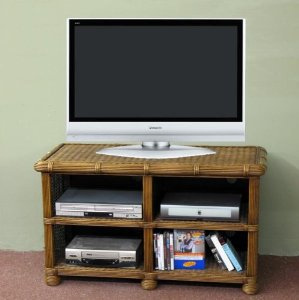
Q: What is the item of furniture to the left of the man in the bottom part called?
A: The piece of furniture is a drawer.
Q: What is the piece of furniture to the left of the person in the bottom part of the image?
A: The piece of furniture is a drawer.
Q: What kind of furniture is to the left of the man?
A: The piece of furniture is a drawer.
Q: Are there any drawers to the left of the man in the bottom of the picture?
A: Yes, there is a drawer to the left of the man.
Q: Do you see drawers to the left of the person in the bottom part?
A: Yes, there is a drawer to the left of the man.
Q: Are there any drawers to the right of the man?
A: No, the drawer is to the left of the man.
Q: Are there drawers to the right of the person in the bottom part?
A: No, the drawer is to the left of the man.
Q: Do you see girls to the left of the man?
A: No, there is a drawer to the left of the man.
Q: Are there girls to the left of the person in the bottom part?
A: No, there is a drawer to the left of the man.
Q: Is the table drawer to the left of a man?
A: Yes, the drawer is to the left of a man.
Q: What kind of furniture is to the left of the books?
A: The piece of furniture is a drawer.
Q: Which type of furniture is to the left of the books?
A: The piece of furniture is a drawer.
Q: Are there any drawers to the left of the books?
A: Yes, there is a drawer to the left of the books.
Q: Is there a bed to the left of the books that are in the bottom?
A: No, there is a drawer to the left of the books.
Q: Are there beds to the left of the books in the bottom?
A: No, there is a drawer to the left of the books.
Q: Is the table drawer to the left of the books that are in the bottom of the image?
A: Yes, the drawer is to the left of the books.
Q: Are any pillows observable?
A: No, there are no pillows.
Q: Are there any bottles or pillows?
A: No, there are no pillows or bottles.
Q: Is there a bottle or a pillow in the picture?
A: No, there are no pillows or bottles.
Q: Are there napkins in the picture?
A: No, there are no napkins.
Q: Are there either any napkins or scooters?
A: No, there are no napkins or scooters.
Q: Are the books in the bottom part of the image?
A: Yes, the books are in the bottom of the image.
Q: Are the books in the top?
A: No, the books are in the bottom of the image.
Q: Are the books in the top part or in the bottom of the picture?
A: The books are in the bottom of the image.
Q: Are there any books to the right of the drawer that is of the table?
A: Yes, there are books to the right of the drawer.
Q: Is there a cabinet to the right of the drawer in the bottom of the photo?
A: No, there are books to the right of the drawer.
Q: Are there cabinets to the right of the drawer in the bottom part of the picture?
A: No, there are books to the right of the drawer.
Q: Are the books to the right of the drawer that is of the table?
A: Yes, the books are to the right of the drawer.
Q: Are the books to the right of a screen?
A: No, the books are to the right of the drawer.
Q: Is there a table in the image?
A: Yes, there is a table.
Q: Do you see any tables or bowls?
A: Yes, there is a table.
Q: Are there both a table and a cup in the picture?
A: No, there is a table but no cups.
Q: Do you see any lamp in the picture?
A: No, there are no lamps.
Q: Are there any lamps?
A: No, there are no lamps.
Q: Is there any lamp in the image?
A: No, there are no lamps.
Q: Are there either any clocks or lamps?
A: No, there are no lamps or clocks.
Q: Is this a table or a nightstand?
A: This is a table.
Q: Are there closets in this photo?
A: No, there are no closets.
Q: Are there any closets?
A: No, there are no closets.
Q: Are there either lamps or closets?
A: No, there are no closets or lamps.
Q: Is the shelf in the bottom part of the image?
A: Yes, the shelf is in the bottom of the image.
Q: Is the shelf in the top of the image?
A: No, the shelf is in the bottom of the image.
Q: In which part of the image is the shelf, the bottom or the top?
A: The shelf is in the bottom of the image.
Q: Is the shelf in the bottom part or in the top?
A: The shelf is in the bottom of the image.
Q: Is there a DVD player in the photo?
A: Yes, there is a DVD player.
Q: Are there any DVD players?
A: Yes, there is a DVD player.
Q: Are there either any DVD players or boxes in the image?
A: Yes, there is a DVD player.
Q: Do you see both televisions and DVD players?
A: Yes, there are both a DVD player and a television.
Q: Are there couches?
A: No, there are no couches.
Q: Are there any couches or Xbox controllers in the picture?
A: No, there are no couches or Xbox controllers.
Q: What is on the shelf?
A: The DVD player is on the shelf.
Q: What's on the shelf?
A: The DVD player is on the shelf.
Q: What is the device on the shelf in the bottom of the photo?
A: The device is a DVD player.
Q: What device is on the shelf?
A: The device is a DVD player.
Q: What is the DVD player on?
A: The DVD player is on the shelf.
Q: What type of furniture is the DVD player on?
A: The DVD player is on the shelf.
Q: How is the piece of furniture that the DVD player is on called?
A: The piece of furniture is a shelf.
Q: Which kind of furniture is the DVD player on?
A: The DVD player is on the shelf.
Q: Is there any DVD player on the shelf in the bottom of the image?
A: Yes, there is a DVD player on the shelf.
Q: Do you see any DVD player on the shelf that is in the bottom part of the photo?
A: Yes, there is a DVD player on the shelf.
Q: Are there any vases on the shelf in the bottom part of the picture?
A: No, there is a DVD player on the shelf.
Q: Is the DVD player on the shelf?
A: Yes, the DVD player is on the shelf.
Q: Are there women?
A: No, there are no women.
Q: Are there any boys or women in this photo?
A: No, there are no women or boys.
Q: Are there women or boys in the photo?
A: No, there are no women or boys.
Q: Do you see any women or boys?
A: No, there are no women or boys.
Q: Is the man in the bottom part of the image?
A: Yes, the man is in the bottom of the image.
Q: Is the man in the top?
A: No, the man is in the bottom of the image.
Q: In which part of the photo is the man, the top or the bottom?
A: The man is in the bottom of the image.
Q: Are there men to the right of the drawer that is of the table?
A: Yes, there is a man to the right of the drawer.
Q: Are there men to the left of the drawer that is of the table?
A: No, the man is to the right of the drawer.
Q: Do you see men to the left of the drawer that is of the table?
A: No, the man is to the right of the drawer.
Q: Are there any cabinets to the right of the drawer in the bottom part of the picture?
A: No, there is a man to the right of the drawer.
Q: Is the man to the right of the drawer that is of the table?
A: Yes, the man is to the right of the drawer.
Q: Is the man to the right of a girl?
A: No, the man is to the right of the drawer.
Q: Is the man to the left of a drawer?
A: No, the man is to the right of a drawer.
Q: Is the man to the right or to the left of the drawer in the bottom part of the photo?
A: The man is to the right of the drawer.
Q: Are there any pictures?
A: No, there are no pictures.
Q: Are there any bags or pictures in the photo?
A: No, there are no pictures or bags.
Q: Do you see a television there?
A: Yes, there is a television.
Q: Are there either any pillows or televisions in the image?
A: Yes, there is a television.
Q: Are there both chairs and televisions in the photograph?
A: No, there is a television but no chairs.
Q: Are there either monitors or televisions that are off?
A: Yes, the television is off.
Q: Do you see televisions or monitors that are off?
A: Yes, the television is off.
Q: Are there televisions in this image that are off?
A: Yes, there is a television that is off.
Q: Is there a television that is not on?
A: Yes, there is a television that is off.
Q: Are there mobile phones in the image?
A: No, there are no mobile phones.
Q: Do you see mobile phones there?
A: No, there are no mobile phones.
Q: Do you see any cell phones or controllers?
A: No, there are no cell phones or controllers.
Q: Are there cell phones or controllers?
A: No, there are no cell phones or controllers.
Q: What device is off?
A: The device is a television.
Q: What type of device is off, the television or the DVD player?
A: The television is off.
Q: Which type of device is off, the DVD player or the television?
A: The television is off.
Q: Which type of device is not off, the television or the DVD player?
A: The DVD player is not off.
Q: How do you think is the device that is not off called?
A: The device is a DVD player.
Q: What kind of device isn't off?
A: The device is a DVD player.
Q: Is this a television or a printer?
A: This is a television.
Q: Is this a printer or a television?
A: This is a television.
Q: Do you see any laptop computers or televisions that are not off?
A: No, there is a television but it is off.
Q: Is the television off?
A: Yes, the television is off.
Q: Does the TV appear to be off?
A: Yes, the TV is off.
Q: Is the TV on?
A: No, the TV is off.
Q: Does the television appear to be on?
A: No, the television is off.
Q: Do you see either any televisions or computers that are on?
A: No, there is a television but it is off.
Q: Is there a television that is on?
A: No, there is a television but it is off.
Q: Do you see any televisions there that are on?
A: No, there is a television but it is off.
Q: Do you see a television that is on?
A: No, there is a television but it is off.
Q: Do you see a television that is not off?
A: No, there is a television but it is off.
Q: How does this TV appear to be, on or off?
A: The TV is off.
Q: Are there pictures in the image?
A: No, there are no pictures.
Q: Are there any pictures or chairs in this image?
A: No, there are no pictures or chairs.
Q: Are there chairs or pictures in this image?
A: No, there are no pictures or chairs.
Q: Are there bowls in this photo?
A: No, there are no bowls.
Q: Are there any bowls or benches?
A: No, there are no bowls or benches.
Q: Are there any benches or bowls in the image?
A: No, there are no bowls or benches.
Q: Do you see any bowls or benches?
A: No, there are no bowls or benches.